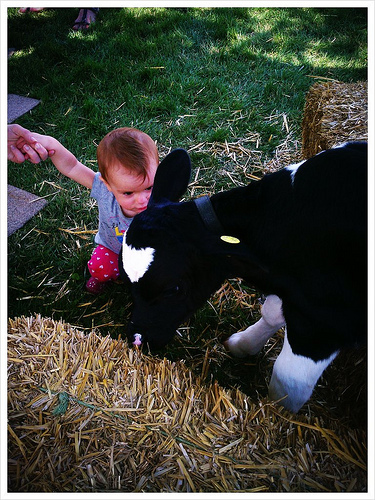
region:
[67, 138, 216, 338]
achild playing with a calf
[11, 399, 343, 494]
a lot of dry grass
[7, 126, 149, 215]
the hand of the adult holding the kid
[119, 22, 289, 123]
green grass in the field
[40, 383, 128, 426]
a piece of green rope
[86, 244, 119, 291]
a red pant with white little hearts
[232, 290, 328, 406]
the two frontal legs of the calf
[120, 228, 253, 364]
the calf is eating grass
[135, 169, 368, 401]
a black calf with whgite spots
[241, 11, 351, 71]
the sunlight reflected on the grass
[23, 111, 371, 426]
baby looking a calf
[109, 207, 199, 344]
calf has a white spot on face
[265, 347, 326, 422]
front leg of calf is white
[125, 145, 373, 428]
calf is white and black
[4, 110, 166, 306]
hand of adult holding a baby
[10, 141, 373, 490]
baby eating hay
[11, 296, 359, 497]
a pack of hay on side a calf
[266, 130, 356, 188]
white spot on back of calf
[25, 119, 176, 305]
baby wears red pants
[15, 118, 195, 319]
baby is sitting squat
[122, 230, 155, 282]
white spot on calf's forehead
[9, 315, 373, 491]
bale of straw hay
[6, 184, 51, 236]
piece of gray carpeting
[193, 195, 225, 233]
blue collar on cow's neck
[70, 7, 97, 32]
woman's foot in sandal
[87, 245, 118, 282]
pink pant with white hearts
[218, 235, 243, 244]
yellow tag in cow's ear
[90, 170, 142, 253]
gray shirt on baby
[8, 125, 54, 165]
hand holding baby's hand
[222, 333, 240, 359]
hoof on calf's leg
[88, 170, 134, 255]
Toddler has on a blue shirt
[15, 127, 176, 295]
The child is looking at a baby calf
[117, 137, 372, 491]
Baby calf is black with white spots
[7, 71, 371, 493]
There are a few bales of hay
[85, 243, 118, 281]
Child has on pink pants with hearts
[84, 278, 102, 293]
Child has on Pink and white shoes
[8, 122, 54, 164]
Someone is hold the child's hand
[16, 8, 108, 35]
There are peoples feet behind the child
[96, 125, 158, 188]
The child has brown hair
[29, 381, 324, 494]
There is a green screen holding the bale of hay together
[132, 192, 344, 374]
the calf is black and white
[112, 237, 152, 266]
the patch is white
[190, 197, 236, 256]
the colar is black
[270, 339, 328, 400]
the legs are white and black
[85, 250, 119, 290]
the pants are red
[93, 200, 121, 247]
the shirt is blue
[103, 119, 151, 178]
the hair is brown red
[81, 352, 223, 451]
the hay is dry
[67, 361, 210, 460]
the hay is brown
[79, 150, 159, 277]
the child is squatting